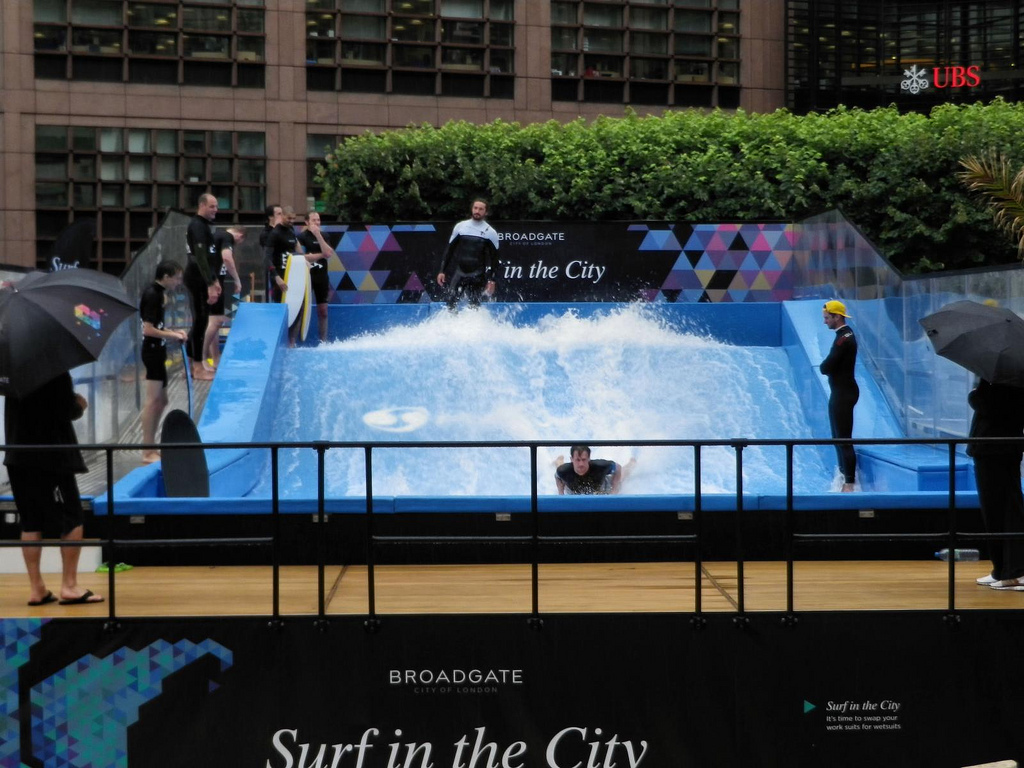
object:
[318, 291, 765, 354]
wavy water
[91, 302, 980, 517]
enclosure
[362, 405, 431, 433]
logo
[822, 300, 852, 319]
cap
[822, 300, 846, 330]
head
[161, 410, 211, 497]
skateboard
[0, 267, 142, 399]
umbrella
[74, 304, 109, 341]
logo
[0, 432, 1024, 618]
railing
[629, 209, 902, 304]
pattern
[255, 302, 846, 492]
water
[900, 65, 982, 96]
name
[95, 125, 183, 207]
blinds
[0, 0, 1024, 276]
building